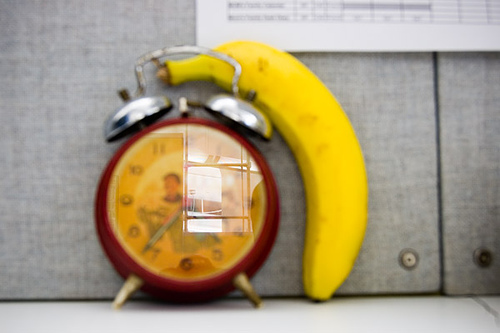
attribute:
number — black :
[241, 192, 261, 217]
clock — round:
[88, 35, 285, 313]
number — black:
[116, 195, 141, 210]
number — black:
[210, 132, 224, 156]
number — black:
[173, 257, 197, 277]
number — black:
[208, 249, 225, 263]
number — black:
[121, 222, 144, 241]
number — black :
[229, 220, 249, 240]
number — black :
[115, 190, 144, 214]